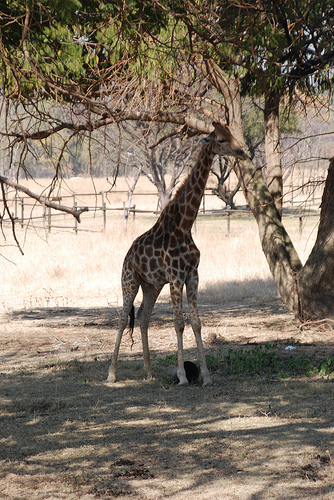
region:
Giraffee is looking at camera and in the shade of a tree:
[106, 119, 241, 364]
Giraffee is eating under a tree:
[137, 115, 263, 240]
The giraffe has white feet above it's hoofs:
[96, 86, 218, 390]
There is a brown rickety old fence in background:
[20, 184, 146, 232]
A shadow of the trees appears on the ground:
[22, 361, 291, 479]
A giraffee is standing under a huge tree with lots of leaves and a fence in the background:
[6, 2, 325, 382]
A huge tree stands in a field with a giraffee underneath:
[0, 39, 326, 435]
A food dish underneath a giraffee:
[171, 349, 244, 398]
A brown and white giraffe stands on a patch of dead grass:
[75, 108, 248, 403]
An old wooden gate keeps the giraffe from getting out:
[0, 113, 313, 231]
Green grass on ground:
[206, 341, 332, 385]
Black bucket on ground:
[161, 356, 211, 390]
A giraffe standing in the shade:
[76, 117, 269, 396]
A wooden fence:
[0, 192, 153, 228]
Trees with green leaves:
[54, 0, 333, 128]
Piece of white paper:
[269, 341, 306, 359]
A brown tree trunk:
[294, 122, 332, 324]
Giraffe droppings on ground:
[72, 451, 175, 498]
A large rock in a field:
[62, 173, 90, 185]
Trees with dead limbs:
[9, 97, 195, 149]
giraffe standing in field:
[105, 120, 248, 388]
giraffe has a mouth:
[239, 152, 249, 161]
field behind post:
[5, 168, 328, 204]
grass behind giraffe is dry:
[0, 214, 278, 304]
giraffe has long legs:
[167, 278, 185, 380]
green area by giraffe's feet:
[203, 336, 326, 379]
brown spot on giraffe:
[150, 233, 161, 243]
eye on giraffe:
[215, 136, 222, 138]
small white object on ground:
[282, 342, 292, 347]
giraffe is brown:
[105, 120, 251, 386]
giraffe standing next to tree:
[106, 121, 247, 386]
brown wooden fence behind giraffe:
[1, 187, 251, 226]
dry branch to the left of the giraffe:
[0, 175, 88, 257]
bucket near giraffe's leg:
[173, 361, 200, 383]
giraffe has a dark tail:
[128, 304, 136, 349]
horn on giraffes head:
[211, 120, 221, 130]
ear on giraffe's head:
[200, 135, 210, 144]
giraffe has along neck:
[157, 148, 217, 227]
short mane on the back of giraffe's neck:
[171, 156, 191, 209]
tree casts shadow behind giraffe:
[10, 276, 284, 328]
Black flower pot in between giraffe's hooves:
[173, 355, 200, 386]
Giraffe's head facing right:
[194, 116, 250, 166]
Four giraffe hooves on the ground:
[97, 353, 220, 392]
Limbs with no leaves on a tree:
[6, 108, 173, 180]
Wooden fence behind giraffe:
[15, 190, 326, 234]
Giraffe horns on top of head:
[202, 117, 232, 133]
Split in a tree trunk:
[254, 239, 332, 325]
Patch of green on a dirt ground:
[212, 340, 327, 371]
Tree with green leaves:
[2, 0, 199, 99]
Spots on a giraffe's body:
[106, 208, 214, 294]